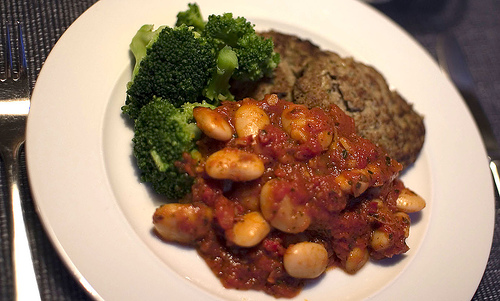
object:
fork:
[0, 19, 43, 301]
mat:
[6, 9, 51, 122]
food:
[119, 2, 426, 300]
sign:
[9, 17, 115, 182]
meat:
[278, 54, 457, 163]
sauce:
[276, 116, 385, 173]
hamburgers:
[259, 27, 425, 167]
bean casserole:
[153, 93, 424, 297]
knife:
[433, 26, 499, 191]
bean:
[260, 179, 312, 234]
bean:
[336, 170, 369, 195]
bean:
[280, 104, 335, 152]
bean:
[235, 105, 270, 137]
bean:
[366, 166, 388, 186]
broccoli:
[123, 6, 273, 196]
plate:
[22, 1, 496, 301]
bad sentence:
[288, 261, 306, 273]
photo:
[2, 0, 484, 297]